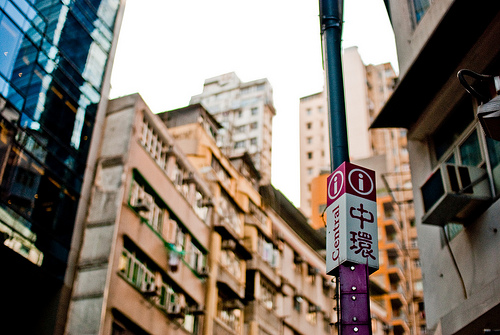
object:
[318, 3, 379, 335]
pole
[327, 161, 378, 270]
sign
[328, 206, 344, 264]
central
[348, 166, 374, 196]
circle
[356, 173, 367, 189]
i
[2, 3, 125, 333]
building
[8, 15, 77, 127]
windows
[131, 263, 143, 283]
window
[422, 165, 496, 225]
air conditioning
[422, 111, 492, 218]
window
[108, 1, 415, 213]
sky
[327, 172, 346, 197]
symbol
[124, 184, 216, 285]
strip